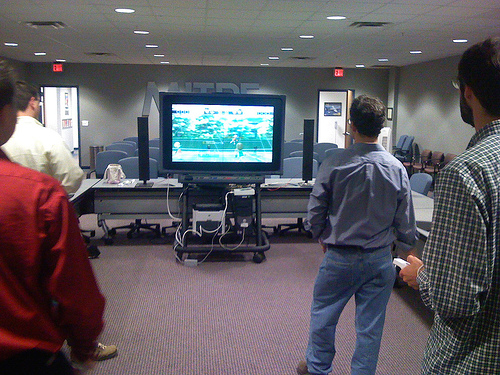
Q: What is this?
A: Room.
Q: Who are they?
A: Men.